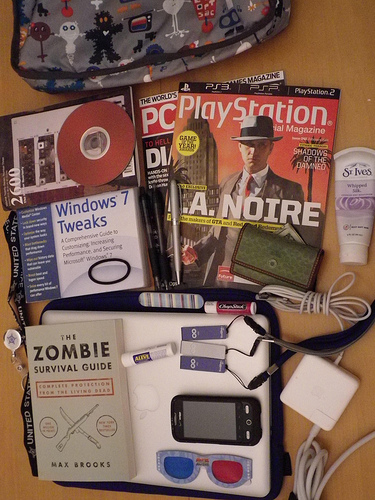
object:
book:
[23, 319, 137, 483]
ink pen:
[165, 175, 186, 286]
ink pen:
[137, 183, 170, 292]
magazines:
[0, 85, 146, 213]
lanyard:
[2, 208, 42, 478]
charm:
[3, 327, 24, 373]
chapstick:
[204, 300, 257, 316]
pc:
[36, 308, 273, 500]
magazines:
[128, 69, 342, 311]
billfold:
[229, 222, 325, 295]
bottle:
[332, 145, 374, 266]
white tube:
[120, 343, 178, 368]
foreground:
[1, 2, 371, 499]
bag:
[10, 0, 292, 96]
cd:
[56, 100, 136, 187]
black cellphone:
[170, 393, 262, 446]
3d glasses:
[156, 448, 253, 489]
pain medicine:
[120, 341, 177, 366]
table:
[0, 0, 375, 499]